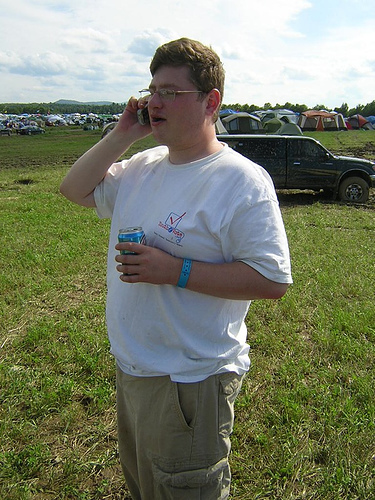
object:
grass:
[298, 322, 372, 400]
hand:
[114, 242, 169, 286]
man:
[58, 35, 292, 498]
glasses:
[139, 88, 203, 103]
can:
[117, 226, 145, 277]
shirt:
[92, 139, 293, 382]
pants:
[109, 365, 244, 500]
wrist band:
[176, 258, 193, 287]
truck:
[213, 134, 375, 202]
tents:
[0, 107, 374, 137]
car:
[16, 125, 46, 136]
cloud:
[0, 0, 124, 71]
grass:
[0, 128, 375, 499]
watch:
[176, 257, 192, 289]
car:
[218, 135, 375, 205]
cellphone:
[137, 102, 152, 126]